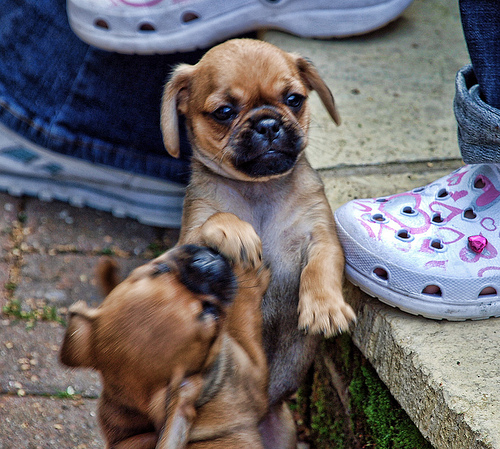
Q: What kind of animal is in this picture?
A: Puppies.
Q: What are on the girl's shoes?
A: Hearts.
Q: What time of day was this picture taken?
A: Day time.